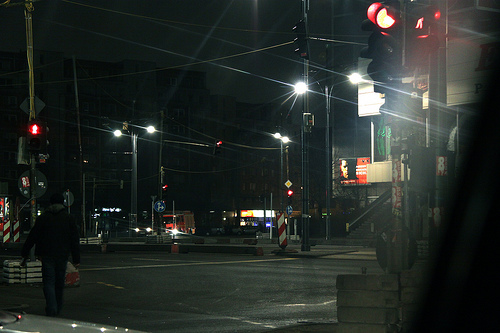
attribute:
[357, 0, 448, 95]
light — red 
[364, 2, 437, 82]
light — red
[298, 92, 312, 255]
pole — metal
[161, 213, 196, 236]
truck — red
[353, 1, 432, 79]
traffic light — red 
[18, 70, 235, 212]
windows — dark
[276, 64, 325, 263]
pole — black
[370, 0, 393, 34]
redlight — red 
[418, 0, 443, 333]
pole — metal 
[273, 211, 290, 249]
caution sign — red and white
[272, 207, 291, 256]
flags — caution flags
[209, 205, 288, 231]
store — corner store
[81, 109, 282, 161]
lines — overhead lines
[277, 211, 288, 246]
sign — red, white, street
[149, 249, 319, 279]
lines — white